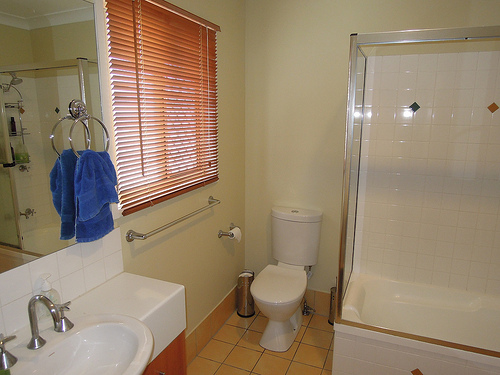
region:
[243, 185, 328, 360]
A white porcelain toilet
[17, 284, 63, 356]
A silver sink faucet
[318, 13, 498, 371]
A bathtub and shower with a glass door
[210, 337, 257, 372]
A beige tiled bathroom floor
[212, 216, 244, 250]
A silver metal toilet paper dispenser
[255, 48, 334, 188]
A white wall surface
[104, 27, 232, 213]
A brown window blind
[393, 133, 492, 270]
White tile in a shower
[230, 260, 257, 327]
A silver metal trash can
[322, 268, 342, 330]
A toilet brush holder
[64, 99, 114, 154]
A metal towel ring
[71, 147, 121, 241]
A blue towel in the ring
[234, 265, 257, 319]
A small metal container on the floor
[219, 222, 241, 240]
A silver toilet paper holder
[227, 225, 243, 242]
A roll of toilet paper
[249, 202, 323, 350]
A small white toilet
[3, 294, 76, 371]
Metal bathroom sink fixtures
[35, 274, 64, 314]
A soap dispenser on the counter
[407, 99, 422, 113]
A diamond pattern in the tiles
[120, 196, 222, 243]
A metal towel rack on the wall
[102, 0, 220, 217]
Blinds hang from window.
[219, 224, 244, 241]
Toilet paper holder and toilet paper.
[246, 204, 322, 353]
White toilet in bathroom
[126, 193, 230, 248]
Metal towel rail on the wall.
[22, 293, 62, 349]
Metal bathroom sink faucet.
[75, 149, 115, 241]
Blue towel on metal holder.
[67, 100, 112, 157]
Round towel holder on mirror.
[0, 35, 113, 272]
Bathroom mirror on wall.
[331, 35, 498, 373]
Shower stall and bathtub.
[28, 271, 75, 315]
Bottle with hand pump on counter.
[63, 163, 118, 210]
towel is blue in color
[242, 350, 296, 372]
the floor is brown in color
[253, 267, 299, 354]
toilet seat is closed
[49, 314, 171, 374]
sink is white in color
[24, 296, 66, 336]
the tap is silvery in color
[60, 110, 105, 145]
towel hanger are silvery in color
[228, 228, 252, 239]
tissue is white in color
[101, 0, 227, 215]
blinds on the window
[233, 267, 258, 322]
silver trash can in the corner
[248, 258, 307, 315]
toilet lid is down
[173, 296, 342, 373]
tile on the floor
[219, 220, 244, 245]
silver toilet paper holder on the wall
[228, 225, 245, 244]
roll of toilet paper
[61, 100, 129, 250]
blue hand towel hanging on a ring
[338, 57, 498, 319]
white tile on the shower wall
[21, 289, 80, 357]
silver faucet hanging over the sink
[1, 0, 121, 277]
mirror on the wall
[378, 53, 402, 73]
small white wall tiles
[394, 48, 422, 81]
small white wall tiles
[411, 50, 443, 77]
small white wall tiles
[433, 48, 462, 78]
small white wall tiles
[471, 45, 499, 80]
small white wall tiles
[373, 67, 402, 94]
small white wall tiles